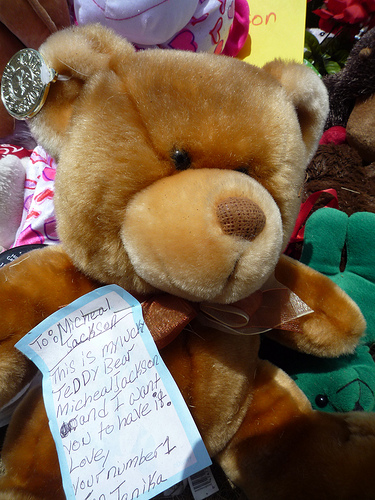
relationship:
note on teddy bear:
[15, 284, 214, 500] [4, 26, 375, 499]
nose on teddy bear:
[216, 196, 269, 239] [4, 26, 375, 499]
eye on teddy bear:
[169, 148, 192, 169] [4, 26, 375, 499]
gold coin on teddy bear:
[4, 47, 50, 118] [4, 26, 375, 499]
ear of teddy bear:
[36, 30, 118, 153] [4, 26, 375, 499]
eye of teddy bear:
[234, 164, 254, 176] [4, 26, 375, 499]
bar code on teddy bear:
[188, 473, 221, 496] [4, 26, 375, 499]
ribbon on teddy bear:
[131, 292, 308, 336] [4, 26, 375, 499]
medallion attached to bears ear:
[4, 47, 50, 118] [36, 30, 118, 153]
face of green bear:
[297, 357, 372, 408] [284, 211, 374, 407]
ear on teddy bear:
[36, 30, 118, 153] [4, 26, 375, 499]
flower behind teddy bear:
[312, 2, 355, 29] [4, 26, 375, 499]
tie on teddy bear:
[131, 292, 308, 336] [4, 26, 375, 499]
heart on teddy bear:
[167, 32, 199, 51] [1, 1, 246, 245]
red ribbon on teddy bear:
[293, 189, 331, 237] [305, 47, 371, 233]